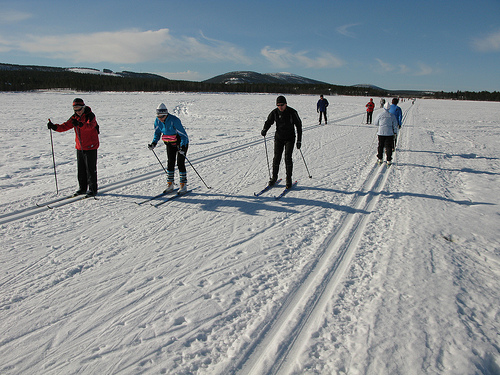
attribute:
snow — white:
[0, 91, 492, 361]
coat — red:
[49, 109, 109, 151]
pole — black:
[280, 134, 347, 219]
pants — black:
[161, 144, 190, 184]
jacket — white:
[362, 91, 413, 146]